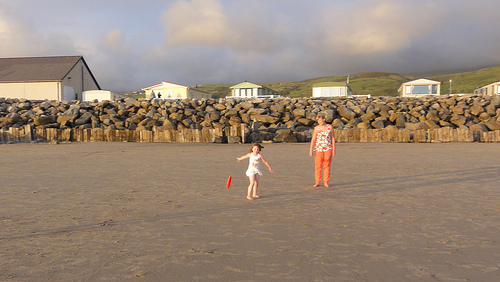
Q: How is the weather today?
A: It is cloudy.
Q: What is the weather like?
A: It is cloudy.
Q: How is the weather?
A: It is cloudy.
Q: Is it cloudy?
A: Yes, it is cloudy.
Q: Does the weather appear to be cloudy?
A: Yes, it is cloudy.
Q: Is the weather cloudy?
A: Yes, it is cloudy.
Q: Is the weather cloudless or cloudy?
A: It is cloudy.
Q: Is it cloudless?
A: No, it is cloudy.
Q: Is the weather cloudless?
A: No, it is cloudy.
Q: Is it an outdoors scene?
A: Yes, it is outdoors.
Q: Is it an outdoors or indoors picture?
A: It is outdoors.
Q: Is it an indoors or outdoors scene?
A: It is outdoors.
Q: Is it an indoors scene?
A: No, it is outdoors.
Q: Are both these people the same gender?
A: Yes, all the people are female.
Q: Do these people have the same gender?
A: Yes, all the people are female.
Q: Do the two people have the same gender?
A: Yes, all the people are female.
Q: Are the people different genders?
A: No, all the people are female.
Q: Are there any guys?
A: No, there are no guys.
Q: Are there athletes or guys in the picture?
A: No, there are no guys or athletes.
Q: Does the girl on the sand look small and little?
A: Yes, the girl is small and little.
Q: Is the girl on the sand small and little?
A: Yes, the girl is small and little.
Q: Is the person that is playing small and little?
A: Yes, the girl is small and little.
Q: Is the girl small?
A: Yes, the girl is small.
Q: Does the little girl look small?
A: Yes, the girl is small.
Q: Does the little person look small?
A: Yes, the girl is small.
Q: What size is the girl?
A: The girl is small.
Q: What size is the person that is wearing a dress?
A: The girl is small.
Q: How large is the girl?
A: The girl is small.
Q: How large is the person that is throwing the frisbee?
A: The girl is small.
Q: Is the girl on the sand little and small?
A: Yes, the girl is little and small.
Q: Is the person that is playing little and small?
A: Yes, the girl is little and small.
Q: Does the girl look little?
A: Yes, the girl is little.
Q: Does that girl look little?
A: Yes, the girl is little.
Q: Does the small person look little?
A: Yes, the girl is little.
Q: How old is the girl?
A: The girl is little.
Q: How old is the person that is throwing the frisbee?
A: The girl is little.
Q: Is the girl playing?
A: Yes, the girl is playing.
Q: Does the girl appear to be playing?
A: Yes, the girl is playing.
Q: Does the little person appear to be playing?
A: Yes, the girl is playing.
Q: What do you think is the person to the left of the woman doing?
A: The girl is playing.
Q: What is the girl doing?
A: The girl is playing.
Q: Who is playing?
A: The girl is playing.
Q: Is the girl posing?
A: No, the girl is playing.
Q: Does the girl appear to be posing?
A: No, the girl is playing.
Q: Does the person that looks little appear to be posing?
A: No, the girl is playing.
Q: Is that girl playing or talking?
A: The girl is playing.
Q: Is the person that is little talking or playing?
A: The girl is playing.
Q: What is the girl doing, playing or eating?
A: The girl is playing.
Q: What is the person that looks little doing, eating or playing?
A: The girl is playing.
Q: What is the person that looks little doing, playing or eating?
A: The girl is playing.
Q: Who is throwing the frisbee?
A: The girl is throwing the frisbee.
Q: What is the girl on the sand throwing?
A: The girl is throwing the frisbee.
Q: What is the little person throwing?
A: The girl is throwing the frisbee.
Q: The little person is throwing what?
A: The girl is throwing the frisbee.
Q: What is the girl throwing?
A: The girl is throwing the frisbee.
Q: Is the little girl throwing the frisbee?
A: Yes, the girl is throwing the frisbee.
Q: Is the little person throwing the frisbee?
A: Yes, the girl is throwing the frisbee.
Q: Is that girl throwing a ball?
A: No, the girl is throwing the frisbee.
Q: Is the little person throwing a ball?
A: No, the girl is throwing the frisbee.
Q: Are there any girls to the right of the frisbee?
A: Yes, there is a girl to the right of the frisbee.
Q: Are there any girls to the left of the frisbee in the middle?
A: No, the girl is to the right of the frisbee.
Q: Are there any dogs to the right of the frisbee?
A: No, there is a girl to the right of the frisbee.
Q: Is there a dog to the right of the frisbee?
A: No, there is a girl to the right of the frisbee.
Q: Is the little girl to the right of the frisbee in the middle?
A: Yes, the girl is to the right of the frisbee.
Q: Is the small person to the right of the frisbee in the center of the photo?
A: Yes, the girl is to the right of the frisbee.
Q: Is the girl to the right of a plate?
A: No, the girl is to the right of the frisbee.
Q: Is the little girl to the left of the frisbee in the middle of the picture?
A: No, the girl is to the right of the frisbee.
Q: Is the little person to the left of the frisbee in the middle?
A: No, the girl is to the right of the frisbee.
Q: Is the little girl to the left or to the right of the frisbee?
A: The girl is to the right of the frisbee.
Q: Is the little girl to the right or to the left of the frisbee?
A: The girl is to the right of the frisbee.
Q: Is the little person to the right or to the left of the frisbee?
A: The girl is to the right of the frisbee.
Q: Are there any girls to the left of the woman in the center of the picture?
A: Yes, there is a girl to the left of the woman.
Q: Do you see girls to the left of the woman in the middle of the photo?
A: Yes, there is a girl to the left of the woman.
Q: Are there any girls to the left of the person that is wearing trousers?
A: Yes, there is a girl to the left of the woman.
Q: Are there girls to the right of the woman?
A: No, the girl is to the left of the woman.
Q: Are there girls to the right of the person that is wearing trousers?
A: No, the girl is to the left of the woman.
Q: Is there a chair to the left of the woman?
A: No, there is a girl to the left of the woman.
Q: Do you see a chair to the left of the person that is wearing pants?
A: No, there is a girl to the left of the woman.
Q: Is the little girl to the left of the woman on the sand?
A: Yes, the girl is to the left of the woman.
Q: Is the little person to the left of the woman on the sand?
A: Yes, the girl is to the left of the woman.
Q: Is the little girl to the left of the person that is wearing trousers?
A: Yes, the girl is to the left of the woman.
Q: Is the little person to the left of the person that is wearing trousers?
A: Yes, the girl is to the left of the woman.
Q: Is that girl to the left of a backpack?
A: No, the girl is to the left of the woman.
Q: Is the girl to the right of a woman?
A: No, the girl is to the left of a woman.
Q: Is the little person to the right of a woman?
A: No, the girl is to the left of a woman.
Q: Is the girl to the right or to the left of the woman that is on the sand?
A: The girl is to the left of the woman.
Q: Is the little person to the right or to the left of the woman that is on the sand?
A: The girl is to the left of the woman.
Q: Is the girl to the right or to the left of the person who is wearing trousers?
A: The girl is to the left of the woman.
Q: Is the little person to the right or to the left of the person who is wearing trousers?
A: The girl is to the left of the woman.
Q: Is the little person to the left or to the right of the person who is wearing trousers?
A: The girl is to the left of the woman.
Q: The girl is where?
A: The girl is on the sand.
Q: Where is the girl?
A: The girl is on the sand.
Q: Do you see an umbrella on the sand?
A: No, there is a girl on the sand.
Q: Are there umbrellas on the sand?
A: No, there is a girl on the sand.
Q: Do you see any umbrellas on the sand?
A: No, there is a girl on the sand.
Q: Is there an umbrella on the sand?
A: No, there is a girl on the sand.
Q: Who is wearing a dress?
A: The girl is wearing a dress.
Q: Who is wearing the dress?
A: The girl is wearing a dress.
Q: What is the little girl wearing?
A: The girl is wearing a dress.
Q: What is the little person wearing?
A: The girl is wearing a dress.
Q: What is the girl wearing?
A: The girl is wearing a dress.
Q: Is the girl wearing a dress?
A: Yes, the girl is wearing a dress.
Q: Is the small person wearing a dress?
A: Yes, the girl is wearing a dress.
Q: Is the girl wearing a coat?
A: No, the girl is wearing a dress.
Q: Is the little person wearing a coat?
A: No, the girl is wearing a dress.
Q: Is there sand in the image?
A: Yes, there is sand.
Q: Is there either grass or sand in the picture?
A: Yes, there is sand.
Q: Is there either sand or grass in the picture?
A: Yes, there is sand.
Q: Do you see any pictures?
A: No, there are no pictures.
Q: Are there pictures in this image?
A: No, there are no pictures.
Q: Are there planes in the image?
A: No, there are no planes.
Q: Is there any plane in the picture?
A: No, there are no airplanes.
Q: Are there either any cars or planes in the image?
A: No, there are no planes or cars.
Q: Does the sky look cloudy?
A: Yes, the sky is cloudy.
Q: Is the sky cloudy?
A: Yes, the sky is cloudy.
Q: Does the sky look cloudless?
A: No, the sky is cloudy.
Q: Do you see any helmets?
A: No, there are no helmets.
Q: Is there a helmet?
A: No, there are no helmets.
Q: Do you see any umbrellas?
A: No, there are no umbrellas.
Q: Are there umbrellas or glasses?
A: No, there are no umbrellas or glasses.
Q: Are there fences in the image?
A: Yes, there is a fence.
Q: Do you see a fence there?
A: Yes, there is a fence.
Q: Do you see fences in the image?
A: Yes, there is a fence.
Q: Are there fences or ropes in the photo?
A: Yes, there is a fence.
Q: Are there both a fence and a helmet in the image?
A: No, there is a fence but no helmets.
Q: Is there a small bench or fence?
A: Yes, there is a small fence.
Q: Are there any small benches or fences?
A: Yes, there is a small fence.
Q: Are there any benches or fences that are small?
A: Yes, the fence is small.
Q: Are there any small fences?
A: Yes, there is a small fence.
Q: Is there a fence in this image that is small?
A: Yes, there is a fence that is small.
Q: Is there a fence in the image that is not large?
A: Yes, there is a small fence.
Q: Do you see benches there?
A: No, there are no benches.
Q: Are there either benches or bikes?
A: No, there are no benches or bikes.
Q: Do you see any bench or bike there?
A: No, there are no benches or bikes.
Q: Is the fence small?
A: Yes, the fence is small.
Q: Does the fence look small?
A: Yes, the fence is small.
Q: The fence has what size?
A: The fence is small.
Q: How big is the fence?
A: The fence is small.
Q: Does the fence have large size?
A: No, the fence is small.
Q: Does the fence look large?
A: No, the fence is small.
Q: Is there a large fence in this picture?
A: No, there is a fence but it is small.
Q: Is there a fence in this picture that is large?
A: No, there is a fence but it is small.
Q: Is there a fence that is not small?
A: No, there is a fence but it is small.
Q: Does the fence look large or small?
A: The fence is small.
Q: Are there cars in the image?
A: No, there are no cars.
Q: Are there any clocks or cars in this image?
A: No, there are no cars or clocks.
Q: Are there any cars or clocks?
A: No, there are no cars or clocks.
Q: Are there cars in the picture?
A: No, there are no cars.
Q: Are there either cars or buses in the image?
A: No, there are no cars or buses.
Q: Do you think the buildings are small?
A: Yes, the buildings are small.